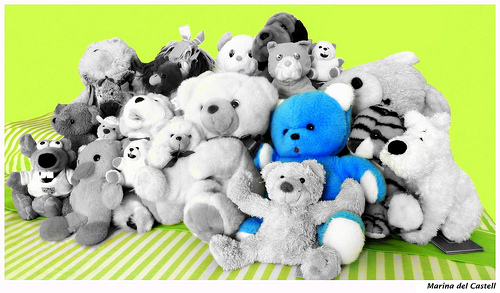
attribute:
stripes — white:
[115, 241, 185, 281]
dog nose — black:
[388, 140, 407, 152]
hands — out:
[227, 175, 366, 210]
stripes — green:
[9, 219, 493, 287]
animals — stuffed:
[52, 32, 448, 254]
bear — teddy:
[271, 91, 352, 153]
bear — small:
[206, 164, 363, 281]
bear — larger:
[235, 81, 387, 268]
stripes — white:
[7, 123, 495, 281]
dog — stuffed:
[378, 105, 483, 243]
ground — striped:
[4, 246, 208, 277]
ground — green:
[10, 123, 498, 276]